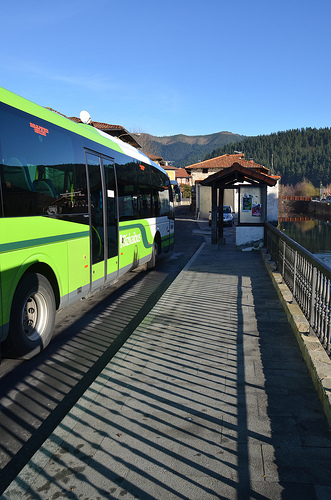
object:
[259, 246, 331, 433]
base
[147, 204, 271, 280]
shadows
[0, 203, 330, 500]
ground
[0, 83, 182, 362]
bus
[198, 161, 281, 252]
stop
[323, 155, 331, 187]
trees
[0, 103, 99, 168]
lights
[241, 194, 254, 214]
flyers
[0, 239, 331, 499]
sidewalk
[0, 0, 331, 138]
sky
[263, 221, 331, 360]
railng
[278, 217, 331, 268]
water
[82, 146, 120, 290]
door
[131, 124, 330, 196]
hill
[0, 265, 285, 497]
shadow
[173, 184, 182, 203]
mirror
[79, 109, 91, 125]
dish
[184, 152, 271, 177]
roof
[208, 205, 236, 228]
car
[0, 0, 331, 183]
background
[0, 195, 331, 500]
bridge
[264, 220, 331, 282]
rail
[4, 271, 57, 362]
tire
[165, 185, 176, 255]
doors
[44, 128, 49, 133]
letters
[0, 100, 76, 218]
glass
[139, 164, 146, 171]
sign